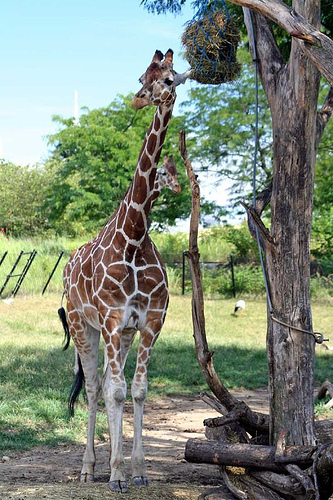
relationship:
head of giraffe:
[128, 48, 196, 114] [87, 50, 225, 205]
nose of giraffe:
[124, 84, 154, 112] [59, 49, 183, 491]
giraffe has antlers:
[59, 49, 192, 495] [150, 46, 174, 69]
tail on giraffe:
[42, 311, 101, 398] [43, 58, 234, 371]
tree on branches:
[238, 0, 331, 444] [170, 137, 236, 382]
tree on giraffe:
[238, 0, 331, 444] [56, 48, 196, 490]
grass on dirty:
[2, 294, 331, 448] [3, 387, 269, 498]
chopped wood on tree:
[183, 394, 330, 499] [238, 0, 331, 444]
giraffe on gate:
[59, 49, 183, 491] [178, 255, 237, 302]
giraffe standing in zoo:
[59, 49, 192, 495] [9, 361, 331, 471]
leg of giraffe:
[86, 409, 164, 500] [63, 362, 158, 483]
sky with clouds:
[19, 10, 102, 60] [16, 125, 77, 186]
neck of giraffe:
[108, 117, 191, 222] [25, 325, 72, 429]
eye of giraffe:
[164, 78, 173, 86] [56, 48, 196, 490]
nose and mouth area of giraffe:
[133, 93, 139, 103] [56, 48, 196, 490]